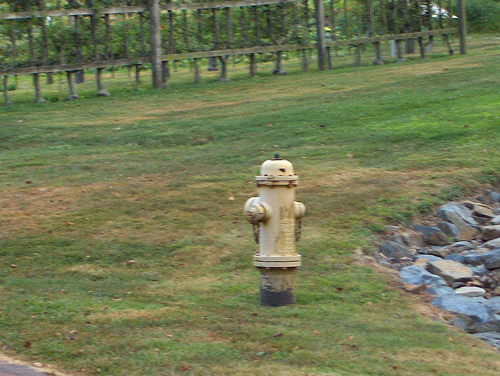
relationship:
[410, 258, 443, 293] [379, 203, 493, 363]
rock in ditch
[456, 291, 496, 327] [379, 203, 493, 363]
rock in ditch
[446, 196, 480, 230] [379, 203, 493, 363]
rock in ditch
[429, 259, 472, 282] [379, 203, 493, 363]
rock in ditch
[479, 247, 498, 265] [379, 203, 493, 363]
rock in ditch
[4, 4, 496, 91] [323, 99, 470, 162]
wooden fence on lawn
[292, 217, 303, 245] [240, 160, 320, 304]
chain on hydrant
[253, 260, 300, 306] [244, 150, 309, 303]
bottom of hydrant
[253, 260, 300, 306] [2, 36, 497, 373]
bottom in ground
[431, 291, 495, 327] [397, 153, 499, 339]
rock in ditch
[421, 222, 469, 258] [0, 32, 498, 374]
rocks piled in grass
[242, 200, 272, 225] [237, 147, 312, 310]
cap on side fire hydrant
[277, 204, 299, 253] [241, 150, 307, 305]
lettering on front fire hydrant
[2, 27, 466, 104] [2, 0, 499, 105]
fence in background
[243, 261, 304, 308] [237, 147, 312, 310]
base on fire hydrant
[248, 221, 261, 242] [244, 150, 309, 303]
chain on hydrant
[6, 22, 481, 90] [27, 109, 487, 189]
fence along grass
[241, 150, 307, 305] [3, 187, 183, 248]
fire hydrant in brown grass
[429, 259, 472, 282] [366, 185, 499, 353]
rock in rock bed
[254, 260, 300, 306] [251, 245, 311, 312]
bottom of fire hydrant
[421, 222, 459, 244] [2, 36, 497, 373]
rocks on ground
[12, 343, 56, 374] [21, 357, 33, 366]
asphalt seen portion